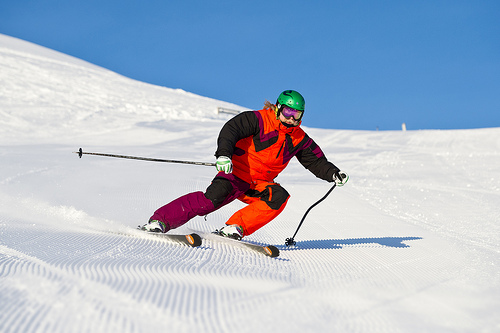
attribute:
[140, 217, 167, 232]
foot — right foot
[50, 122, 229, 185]
pole — ski pole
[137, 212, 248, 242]
shoes — white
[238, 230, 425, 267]
shadow — skier's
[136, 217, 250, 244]
ski boots — white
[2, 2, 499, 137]
sky — clear blue, overhead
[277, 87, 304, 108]
helmet — green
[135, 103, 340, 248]
winter suit — orange, black, purple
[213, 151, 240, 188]
hand — right hand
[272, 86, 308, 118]
helmet — green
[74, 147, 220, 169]
ski pole — extended out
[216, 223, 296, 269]
ski — black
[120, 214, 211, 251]
ski — black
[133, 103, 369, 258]
suit — orange, purple, black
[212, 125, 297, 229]
suit — winter suit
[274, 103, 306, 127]
goggles — reflective goggles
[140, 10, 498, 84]
sky — clear, blue, sunny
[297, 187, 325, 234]
ski pole — crooked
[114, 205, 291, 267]
skis — silver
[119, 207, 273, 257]
skis — black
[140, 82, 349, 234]
skier — on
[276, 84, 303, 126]
helmet — green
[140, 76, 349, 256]
person — black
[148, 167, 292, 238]
pants — red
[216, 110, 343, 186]
ski jacket — orange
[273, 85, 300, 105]
helmet — green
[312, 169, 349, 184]
gloves — white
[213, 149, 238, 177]
gloves — white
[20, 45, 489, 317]
ski slope — snowy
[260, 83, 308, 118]
helmet — green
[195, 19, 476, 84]
sky — clear , blue 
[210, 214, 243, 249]
foot — left foot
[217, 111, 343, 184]
sleeves — black